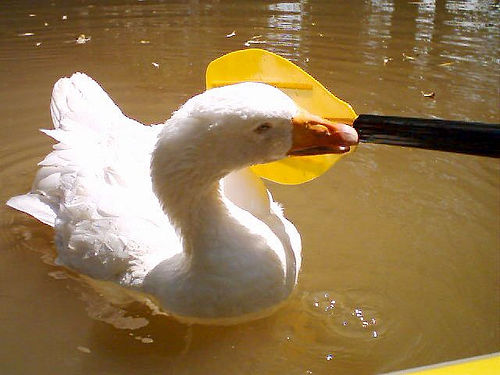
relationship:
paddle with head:
[204, 48, 500, 186] [119, 44, 331, 193]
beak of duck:
[285, 114, 362, 156] [3, 67, 347, 331]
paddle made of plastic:
[204, 47, 498, 187] [204, 49, 356, 187]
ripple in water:
[307, 290, 429, 360] [314, 198, 457, 347]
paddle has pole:
[204, 47, 498, 187] [354, 112, 499, 157]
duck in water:
[4, 71, 359, 326] [1, 1, 499, 373]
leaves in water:
[23, 18, 102, 56] [139, 16, 484, 113]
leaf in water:
[354, 43, 404, 92] [139, 16, 484, 113]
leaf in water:
[408, 75, 448, 110] [139, 16, 484, 113]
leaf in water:
[437, 43, 467, 83] [139, 16, 484, 113]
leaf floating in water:
[139, 35, 152, 47] [1, 1, 499, 373]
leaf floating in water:
[71, 29, 92, 48] [1, 1, 499, 373]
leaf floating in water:
[16, 27, 36, 39] [1, 1, 499, 373]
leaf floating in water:
[145, 55, 165, 72] [1, 1, 499, 373]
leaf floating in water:
[60, 10, 71, 24] [1, 1, 499, 373]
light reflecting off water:
[271, 4, 307, 62] [1, 1, 499, 373]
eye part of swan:
[252, 122, 272, 135] [4, 61, 360, 326]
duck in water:
[3, 67, 347, 331] [1, 1, 499, 373]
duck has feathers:
[3, 67, 347, 331] [95, 158, 136, 207]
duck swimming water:
[4, 71, 359, 326] [308, 14, 445, 110]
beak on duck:
[285, 114, 358, 156] [3, 67, 347, 331]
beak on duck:
[285, 114, 358, 156] [118, 99, 382, 300]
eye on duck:
[250, 118, 276, 135] [15, 56, 365, 330]